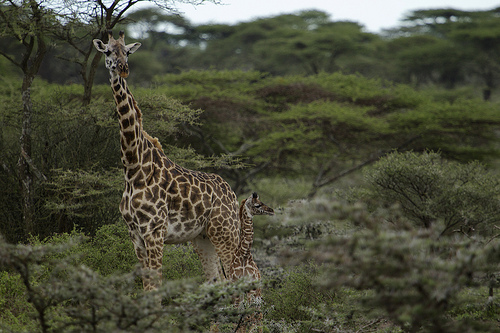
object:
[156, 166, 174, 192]
pattern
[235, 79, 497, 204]
trees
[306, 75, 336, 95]
leaves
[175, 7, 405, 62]
sky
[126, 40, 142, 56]
ears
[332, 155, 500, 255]
brush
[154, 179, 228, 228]
spots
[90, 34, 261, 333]
zebra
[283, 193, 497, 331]
bushes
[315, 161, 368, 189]
black branch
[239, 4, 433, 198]
tree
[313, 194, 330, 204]
white moss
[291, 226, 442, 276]
tree top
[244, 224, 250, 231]
brown comb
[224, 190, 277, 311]
baby giraffe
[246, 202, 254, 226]
small stripes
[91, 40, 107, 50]
black spot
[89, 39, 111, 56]
ear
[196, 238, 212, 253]
white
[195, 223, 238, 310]
leg